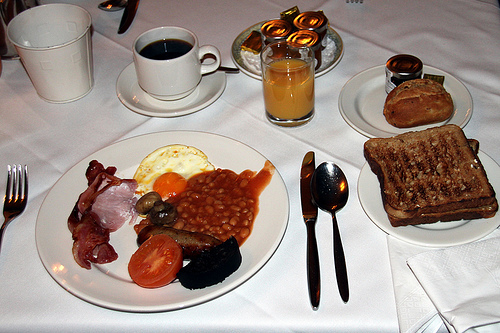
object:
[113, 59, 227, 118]
saucer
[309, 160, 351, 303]
spoon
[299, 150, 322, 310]
knife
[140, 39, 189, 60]
coffee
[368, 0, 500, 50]
white cloth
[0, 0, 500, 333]
table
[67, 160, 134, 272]
bacon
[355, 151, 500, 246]
saucer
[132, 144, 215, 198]
egg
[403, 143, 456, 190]
bread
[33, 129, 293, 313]
white plate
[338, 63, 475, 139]
saucer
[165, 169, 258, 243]
beans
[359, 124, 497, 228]
toast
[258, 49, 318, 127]
glass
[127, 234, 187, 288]
tomato slice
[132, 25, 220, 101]
cup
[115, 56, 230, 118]
white saucer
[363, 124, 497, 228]
bread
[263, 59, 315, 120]
juice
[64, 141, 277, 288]
soup